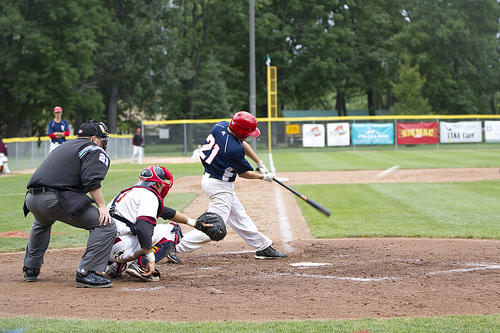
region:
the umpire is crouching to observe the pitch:
[18, 115, 122, 291]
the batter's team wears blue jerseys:
[193, 116, 258, 183]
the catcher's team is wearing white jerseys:
[98, 181, 179, 266]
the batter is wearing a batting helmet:
[225, 105, 265, 141]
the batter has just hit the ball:
[370, 157, 407, 184]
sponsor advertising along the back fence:
[281, 114, 499, 146]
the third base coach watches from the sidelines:
[43, 100, 75, 151]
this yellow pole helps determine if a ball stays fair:
[262, 58, 281, 153]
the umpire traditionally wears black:
[18, 117, 119, 289]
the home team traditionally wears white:
[107, 181, 183, 271]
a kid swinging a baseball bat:
[165, 110, 332, 259]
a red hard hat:
[226, 112, 261, 141]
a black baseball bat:
[253, 165, 330, 218]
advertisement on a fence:
[299, 120, 499, 148]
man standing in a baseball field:
[47, 103, 71, 149]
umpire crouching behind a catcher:
[22, 123, 118, 290]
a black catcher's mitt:
[198, 209, 226, 240]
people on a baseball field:
[3, 105, 330, 284]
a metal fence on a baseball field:
[143, 121, 499, 152]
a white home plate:
[290, 259, 332, 266]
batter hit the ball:
[169, 85, 357, 271]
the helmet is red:
[216, 99, 278, 147]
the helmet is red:
[191, 83, 294, 170]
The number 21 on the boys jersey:
[192, 132, 224, 167]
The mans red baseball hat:
[228, 96, 262, 140]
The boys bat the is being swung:
[252, 162, 333, 222]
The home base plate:
[300, 258, 334, 278]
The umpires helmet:
[147, 165, 167, 203]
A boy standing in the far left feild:
[47, 105, 64, 147]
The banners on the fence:
[300, 119, 498, 149]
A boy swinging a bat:
[185, 113, 336, 265]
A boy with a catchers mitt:
[104, 152, 234, 277]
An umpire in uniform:
[31, 125, 126, 309]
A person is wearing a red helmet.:
[218, 99, 265, 144]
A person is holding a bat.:
[231, 141, 363, 256]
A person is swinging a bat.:
[230, 150, 357, 221]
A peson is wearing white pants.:
[207, 182, 276, 235]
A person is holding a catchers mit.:
[190, 210, 234, 248]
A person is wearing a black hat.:
[65, 113, 133, 141]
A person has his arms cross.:
[40, 109, 82, 153]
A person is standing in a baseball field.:
[42, 89, 72, 155]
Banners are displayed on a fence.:
[294, 118, 499, 147]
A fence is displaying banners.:
[296, 116, 485, 157]